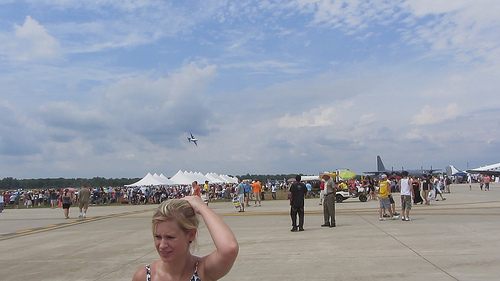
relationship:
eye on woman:
[163, 234, 176, 240] [111, 192, 251, 277]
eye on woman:
[153, 231, 163, 241] [111, 192, 251, 277]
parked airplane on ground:
[363, 154, 441, 182] [2, 182, 499, 279]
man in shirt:
[397, 171, 419, 220] [400, 177, 411, 194]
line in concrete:
[454, 208, 478, 218] [423, 220, 497, 235]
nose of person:
[154, 231, 172, 248] [125, 192, 242, 279]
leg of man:
[402, 203, 415, 223] [397, 171, 419, 220]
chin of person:
[157, 250, 182, 260] [134, 197, 240, 281]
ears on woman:
[187, 220, 195, 242] [113, 172, 241, 279]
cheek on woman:
[169, 233, 190, 256] [152, 183, 238, 275]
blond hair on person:
[151, 199, 202, 240] [134, 197, 240, 281]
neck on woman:
[155, 246, 193, 268] [110, 160, 226, 280]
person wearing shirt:
[134, 197, 240, 281] [142, 259, 203, 281]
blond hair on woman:
[151, 199, 202, 240] [120, 186, 244, 278]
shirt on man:
[289, 181, 308, 223] [276, 170, 313, 235]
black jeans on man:
[291, 205, 304, 227] [289, 173, 307, 232]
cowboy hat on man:
[319, 172, 341, 213] [314, 165, 342, 229]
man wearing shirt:
[322, 173, 347, 226] [252, 179, 266, 199]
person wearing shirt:
[134, 197, 240, 281] [182, 259, 203, 278]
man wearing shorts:
[376, 175, 395, 218] [374, 195, 394, 208]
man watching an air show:
[376, 175, 395, 218] [1, 3, 484, 279]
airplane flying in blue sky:
[184, 130, 202, 149] [184, 129, 201, 149]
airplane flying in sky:
[184, 130, 202, 149] [1, 5, 484, 156]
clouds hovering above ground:
[117, 59, 220, 133] [403, 136, 447, 173]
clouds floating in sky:
[117, 59, 220, 133] [171, 33, 237, 86]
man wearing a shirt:
[376, 175, 395, 218] [373, 177, 393, 197]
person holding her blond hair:
[104, 197, 241, 279] [151, 199, 199, 232]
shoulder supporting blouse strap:
[132, 257, 158, 276] [144, 262, 152, 279]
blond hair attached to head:
[151, 199, 202, 240] [151, 196, 197, 263]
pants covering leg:
[289, 200, 309, 230] [288, 206, 298, 232]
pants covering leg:
[322, 192, 338, 223] [329, 205, 336, 229]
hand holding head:
[180, 193, 210, 214] [148, 197, 200, 264]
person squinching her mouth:
[134, 197, 240, 281] [156, 247, 176, 257]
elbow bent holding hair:
[218, 234, 243, 254] [151, 197, 199, 233]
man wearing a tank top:
[390, 176, 433, 232] [399, 175, 411, 196]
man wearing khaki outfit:
[79, 182, 91, 218] [75, 175, 110, 220]